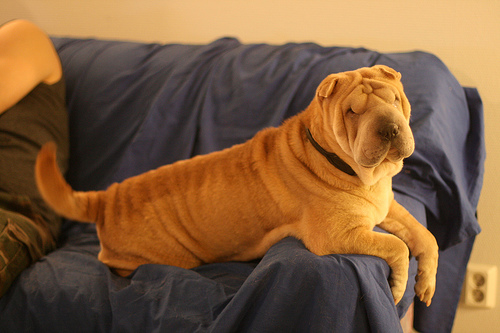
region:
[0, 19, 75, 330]
man sitting next to dog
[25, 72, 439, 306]
dog laying on the couch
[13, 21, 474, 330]
blue sheet on the couch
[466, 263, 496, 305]
white outlet on the wall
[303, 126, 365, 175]
black collar on dog's neck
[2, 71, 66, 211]
gray tank worn by man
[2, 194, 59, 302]
camoflauge pants worn by man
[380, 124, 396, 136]
black nose of the dog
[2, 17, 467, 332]
couch man and dog are sitting on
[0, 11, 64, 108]
arm of man on the couch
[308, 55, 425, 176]
head of a dog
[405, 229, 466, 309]
leg of a dog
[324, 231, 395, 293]
leg of a dog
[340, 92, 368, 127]
eye of a dog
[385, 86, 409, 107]
eye of a dog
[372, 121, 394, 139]
nose of a dog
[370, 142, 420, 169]
mouth of a dog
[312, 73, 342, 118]
ear of a dog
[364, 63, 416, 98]
ear of a dog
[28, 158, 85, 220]
tail of a dog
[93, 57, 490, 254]
a dog on the couch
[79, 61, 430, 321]
a large dog on a couch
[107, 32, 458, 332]
a brown dog on the couch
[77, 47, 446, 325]
a large brown dog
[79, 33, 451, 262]
a large brown dog on a couch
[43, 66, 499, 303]
a dog laying on a couch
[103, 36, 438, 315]
a alrge dog laying on a couch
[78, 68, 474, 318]
a dog wearing a collar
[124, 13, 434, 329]
a couch with a dog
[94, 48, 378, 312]
a dog that is inside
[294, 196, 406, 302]
the tan leg of the dog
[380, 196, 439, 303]
the tan leg of the dog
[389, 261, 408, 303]
the tan paw of the dog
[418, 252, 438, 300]
the tan paw of the dog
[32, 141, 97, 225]
the tan tail of the dog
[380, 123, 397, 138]
the brown nose of the dog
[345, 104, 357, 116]
the black eye of the dog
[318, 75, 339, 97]
the tan ear of the dog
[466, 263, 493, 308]
the light socket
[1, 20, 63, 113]
the arm of the person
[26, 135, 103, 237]
A brown dog toy's tail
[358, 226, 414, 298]
A brown dog toy foot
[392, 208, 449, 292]
A brown dog toy foot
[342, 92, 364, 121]
A brown dog toy' eye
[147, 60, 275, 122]
A blue coach cover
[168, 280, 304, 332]
A blue coach cover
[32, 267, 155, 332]
A blue coach cover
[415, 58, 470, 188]
A blue coach cover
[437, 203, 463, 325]
A blue coach cover